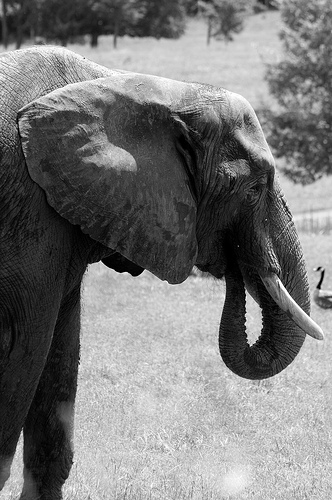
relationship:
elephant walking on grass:
[0, 36, 324, 500] [98, 384, 327, 492]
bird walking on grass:
[313, 266, 332, 313] [98, 384, 327, 492]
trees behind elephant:
[1, 1, 279, 47] [0, 36, 324, 500]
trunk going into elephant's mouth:
[217, 181, 312, 382] [219, 216, 245, 276]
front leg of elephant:
[0, 227, 71, 488] [0, 36, 324, 500]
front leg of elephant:
[18, 284, 80, 498] [0, 36, 324, 500]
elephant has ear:
[0, 36, 324, 500] [15, 72, 208, 286]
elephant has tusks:
[0, 36, 324, 500] [246, 257, 329, 350]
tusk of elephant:
[259, 266, 323, 357] [0, 36, 324, 500]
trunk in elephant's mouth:
[264, 271, 321, 342] [217, 215, 242, 278]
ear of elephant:
[15, 72, 208, 286] [0, 36, 324, 500]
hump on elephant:
[0, 43, 85, 66] [53, 36, 326, 416]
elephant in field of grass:
[0, 36, 324, 500] [0, 12, 330, 498]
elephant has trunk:
[0, 36, 324, 500] [205, 221, 315, 386]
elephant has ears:
[0, 36, 324, 500] [15, 74, 201, 285]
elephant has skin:
[0, 36, 324, 500] [67, 130, 176, 223]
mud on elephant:
[159, 205, 201, 267] [1, 32, 321, 408]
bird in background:
[313, 265, 330, 310] [31, 10, 319, 308]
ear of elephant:
[15, 72, 198, 285] [0, 36, 324, 500]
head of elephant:
[183, 93, 281, 288] [0, 36, 324, 500]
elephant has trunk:
[17, 69, 322, 385] [217, 181, 312, 382]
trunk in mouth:
[217, 181, 312, 382] [196, 241, 250, 293]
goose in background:
[304, 256, 330, 326] [0, 0, 320, 296]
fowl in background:
[313, 265, 331, 309] [0, 4, 321, 351]